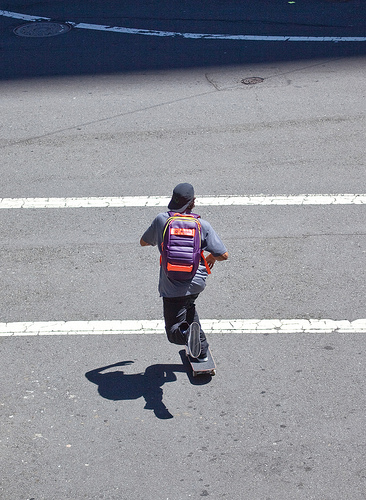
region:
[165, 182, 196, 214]
black hat on a skater's head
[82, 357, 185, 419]
shadow cast on the ground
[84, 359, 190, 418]
skateboarder's shadow on a ground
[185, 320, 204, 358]
the bottom of a shoe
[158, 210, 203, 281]
colorful backpack on a person's back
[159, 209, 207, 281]
red and purple backpack on a man's back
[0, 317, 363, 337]
cracked white line on a street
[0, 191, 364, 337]
two thick cracked lines on a street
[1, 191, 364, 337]
two thick white lines on a street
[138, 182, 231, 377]
person riding a skateboard on a street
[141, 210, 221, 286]
Wearing a book bag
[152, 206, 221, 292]
Orange and purple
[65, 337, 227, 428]
Shadow on the street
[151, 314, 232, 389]
Riding a skateboard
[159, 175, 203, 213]
Cap is backward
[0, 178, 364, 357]
Paint on the ground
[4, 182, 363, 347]
Paint is white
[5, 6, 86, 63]
Gutter on the street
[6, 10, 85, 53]
This is a circle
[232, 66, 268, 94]
A smaller gutter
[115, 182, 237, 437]
man is riding a skateboard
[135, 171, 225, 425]
man is carrying a backpack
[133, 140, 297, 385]
a boy on a skateboard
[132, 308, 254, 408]
a boy wearing shoes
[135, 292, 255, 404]
a boy wearing black pants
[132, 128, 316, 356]
a boy wearing a blue shirt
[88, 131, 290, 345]
a boy wearing a purple bag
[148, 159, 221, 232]
a boy wearing a cap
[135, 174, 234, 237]
a boy wearing a backwards cap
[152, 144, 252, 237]
the back of a boy head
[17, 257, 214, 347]
a white line in the street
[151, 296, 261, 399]
a boy riding a black skate board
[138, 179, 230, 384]
The man is skate boarding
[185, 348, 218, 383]
The skate board is black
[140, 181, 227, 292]
The man is wearing a backpack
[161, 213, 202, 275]
The backpack is purple and orange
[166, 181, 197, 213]
The man is wearing a black hat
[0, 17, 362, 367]
The asphalt has white lines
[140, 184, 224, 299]
Man wearing a grey shirt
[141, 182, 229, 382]
The man is riding the skate board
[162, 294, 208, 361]
Man wearing dark pants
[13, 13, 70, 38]
Grey storm drain cover on asphalt